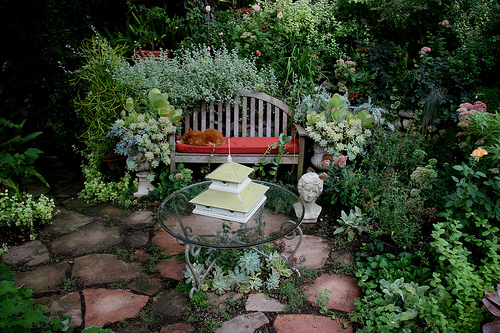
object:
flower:
[470, 147, 488, 157]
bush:
[353, 218, 498, 332]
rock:
[15, 260, 70, 294]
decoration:
[188, 155, 269, 224]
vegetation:
[436, 100, 498, 280]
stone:
[151, 289, 187, 322]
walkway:
[0, 177, 362, 332]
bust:
[293, 172, 324, 224]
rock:
[122, 230, 148, 247]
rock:
[72, 253, 144, 288]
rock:
[50, 221, 123, 257]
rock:
[156, 258, 186, 281]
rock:
[302, 269, 361, 313]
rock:
[272, 314, 353, 332]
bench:
[169, 89, 308, 182]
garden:
[0, 0, 500, 333]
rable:
[157, 180, 305, 300]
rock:
[39, 209, 92, 234]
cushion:
[176, 137, 299, 154]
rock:
[244, 292, 291, 312]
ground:
[0, 174, 361, 333]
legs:
[185, 235, 202, 299]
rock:
[276, 235, 330, 271]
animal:
[183, 129, 226, 146]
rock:
[81, 287, 149, 329]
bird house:
[189, 154, 271, 223]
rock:
[211, 311, 269, 333]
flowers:
[321, 160, 330, 167]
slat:
[242, 96, 248, 137]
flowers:
[319, 172, 328, 179]